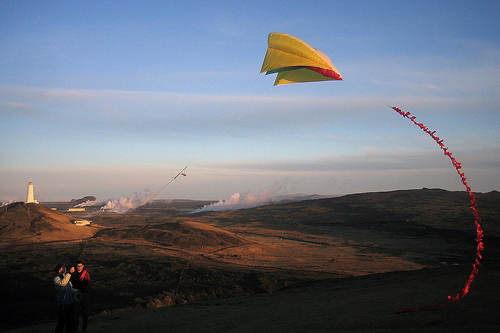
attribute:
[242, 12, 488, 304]
kite — yelloiw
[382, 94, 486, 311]
kite tail — red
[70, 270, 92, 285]
jacket — red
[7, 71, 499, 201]
clouds — white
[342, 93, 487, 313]
tassel — red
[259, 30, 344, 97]
yellow kite — curved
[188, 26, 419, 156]
kite — long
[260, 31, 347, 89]
kite — yellow, red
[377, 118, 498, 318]
ribbon — long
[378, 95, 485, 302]
tail — red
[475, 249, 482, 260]
tassel — red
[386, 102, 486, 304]
tail — red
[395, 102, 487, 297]
tassel — red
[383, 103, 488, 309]
ribbon — red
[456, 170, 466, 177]
tassel — red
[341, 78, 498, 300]
tail — red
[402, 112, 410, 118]
tassel — red, tail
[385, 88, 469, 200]
kite tail — red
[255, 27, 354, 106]
kite — yelloiw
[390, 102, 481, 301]
tassel — red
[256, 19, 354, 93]
kite — green